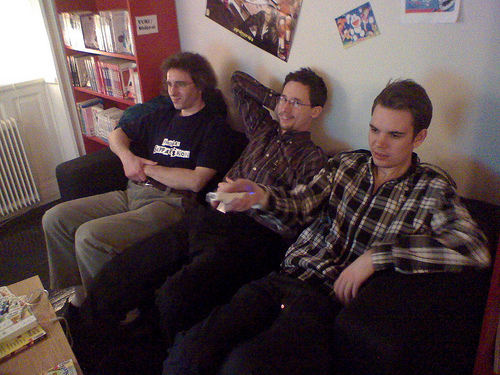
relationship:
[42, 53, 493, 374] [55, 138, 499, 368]
men sitting on couch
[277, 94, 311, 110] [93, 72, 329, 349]
eyeglasses on face of man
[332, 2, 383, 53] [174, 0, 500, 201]
cartoon drawing on wall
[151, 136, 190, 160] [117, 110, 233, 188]
writing on t-shirt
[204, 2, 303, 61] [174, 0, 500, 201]
poster hanging on wall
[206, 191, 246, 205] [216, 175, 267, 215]
remote controller in hand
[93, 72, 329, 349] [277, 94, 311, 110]
man has on eyeglasses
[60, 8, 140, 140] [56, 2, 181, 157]
books on bookshelf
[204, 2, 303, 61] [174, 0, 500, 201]
poster on wall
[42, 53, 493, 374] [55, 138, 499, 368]
men on couch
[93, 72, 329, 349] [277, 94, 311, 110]
man have on eyeglasses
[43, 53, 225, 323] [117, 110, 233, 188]
guy in black t-shirt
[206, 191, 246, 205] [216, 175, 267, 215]
remote controller in mans hand